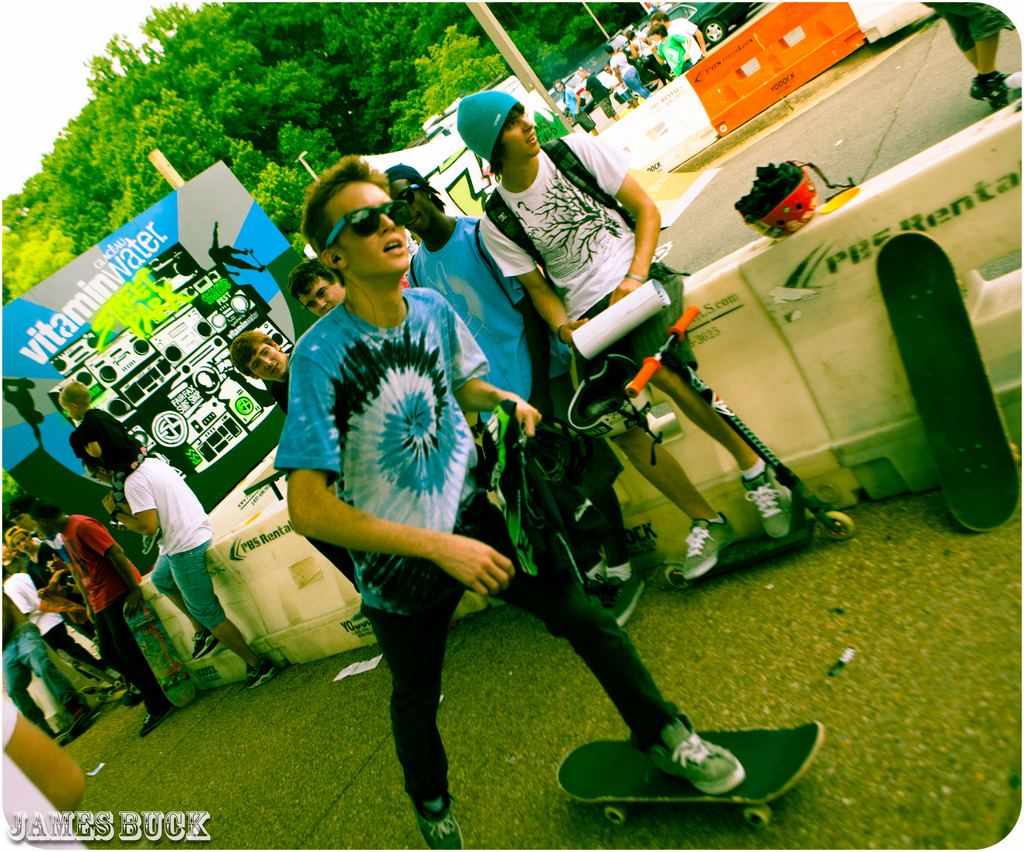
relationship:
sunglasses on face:
[326, 199, 413, 250] [316, 169, 418, 269]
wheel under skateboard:
[597, 796, 621, 825] [551, 716, 824, 829]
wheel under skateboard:
[741, 800, 774, 835] [551, 716, 824, 829]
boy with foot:
[274, 152, 747, 851] [649, 720, 743, 792]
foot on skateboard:
[649, 720, 743, 792] [551, 716, 824, 829]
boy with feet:
[455, 90, 792, 583] [737, 458, 802, 538]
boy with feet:
[455, 90, 792, 583] [679, 512, 738, 577]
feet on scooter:
[737, 458, 802, 538] [623, 301, 859, 585]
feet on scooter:
[679, 512, 738, 577] [623, 301, 859, 585]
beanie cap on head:
[455, 90, 520, 163] [452, 79, 548, 194]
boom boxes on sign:
[39, 235, 292, 473] [17, 227, 296, 509]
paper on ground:
[318, 641, 388, 689] [296, 633, 444, 744]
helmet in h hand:
[564, 350, 655, 454] [569, 307, 608, 366]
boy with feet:
[274, 152, 747, 851] [319, 556, 672, 811]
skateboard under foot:
[555, 721, 824, 828] [649, 717, 747, 796]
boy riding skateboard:
[226, 139, 738, 852] [535, 700, 831, 850]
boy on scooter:
[455, 90, 792, 583] [579, 299, 852, 606]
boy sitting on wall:
[455, 90, 792, 583] [536, 286, 1012, 580]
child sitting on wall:
[57, 379, 145, 531] [192, 521, 361, 666]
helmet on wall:
[720, 168, 839, 249] [569, 212, 997, 405]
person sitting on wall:
[225, 320, 364, 629] [204, 148, 972, 673]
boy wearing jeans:
[274, 152, 747, 851] [380, 529, 677, 808]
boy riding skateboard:
[274, 152, 747, 851] [551, 716, 824, 829]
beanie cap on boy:
[455, 90, 520, 163] [455, 90, 792, 583]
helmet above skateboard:
[732, 158, 828, 238] [866, 227, 1022, 534]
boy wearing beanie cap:
[437, 67, 814, 582] [455, 90, 520, 163]